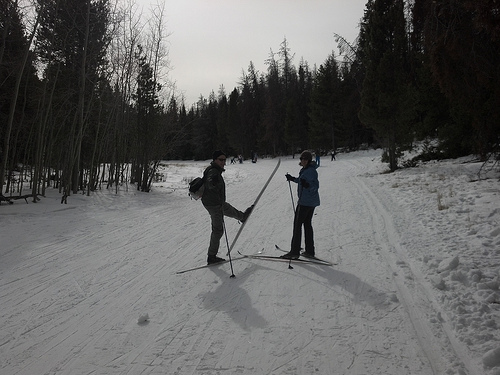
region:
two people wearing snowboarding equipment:
[168, 143, 347, 273]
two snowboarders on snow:
[168, 124, 342, 286]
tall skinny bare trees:
[16, 2, 174, 196]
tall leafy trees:
[178, 30, 383, 152]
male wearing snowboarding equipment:
[171, 135, 282, 271]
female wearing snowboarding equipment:
[261, 141, 337, 274]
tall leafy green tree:
[350, 3, 479, 171]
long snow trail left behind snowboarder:
[343, 135, 413, 358]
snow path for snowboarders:
[170, 150, 380, 358]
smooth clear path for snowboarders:
[161, 159, 396, 374]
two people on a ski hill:
[141, 126, 357, 294]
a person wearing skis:
[183, 130, 283, 270]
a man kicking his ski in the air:
[195, 149, 288, 263]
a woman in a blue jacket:
[278, 145, 328, 266]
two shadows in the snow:
[195, 250, 400, 338]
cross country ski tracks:
[355, 160, 498, 374]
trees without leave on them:
[0, 0, 152, 202]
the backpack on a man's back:
[186, 166, 211, 206]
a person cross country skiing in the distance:
[324, 152, 344, 160]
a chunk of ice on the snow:
[135, 308, 150, 324]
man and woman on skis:
[180, 138, 340, 280]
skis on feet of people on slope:
[173, 238, 332, 278]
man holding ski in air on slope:
[173, 146, 292, 278]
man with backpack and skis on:
[166, 145, 283, 270]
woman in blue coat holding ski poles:
[248, 144, 327, 274]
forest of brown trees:
[5, 0, 193, 219]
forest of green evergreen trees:
[152, 0, 489, 178]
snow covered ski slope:
[6, 141, 499, 363]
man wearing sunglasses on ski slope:
[178, 143, 286, 270]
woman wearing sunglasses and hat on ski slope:
[265, 143, 341, 263]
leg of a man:
[214, 243, 221, 263]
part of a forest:
[92, 148, 113, 163]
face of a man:
[214, 143, 236, 169]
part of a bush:
[430, 138, 438, 148]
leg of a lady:
[296, 243, 303, 267]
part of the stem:
[78, 182, 113, 195]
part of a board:
[194, 261, 203, 273]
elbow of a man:
[308, 179, 318, 184]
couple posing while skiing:
[90, 5, 410, 305]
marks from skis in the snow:
[16, 257, 166, 362]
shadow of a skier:
[200, 265, 267, 336]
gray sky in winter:
[180, 5, 320, 32]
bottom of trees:
[10, 157, 145, 202]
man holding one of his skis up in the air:
[181, 150, 276, 270]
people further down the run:
[225, 140, 262, 165]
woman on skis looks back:
[285, 140, 340, 265]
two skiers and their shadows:
[185, 150, 391, 326]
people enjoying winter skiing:
[63, 5, 434, 321]